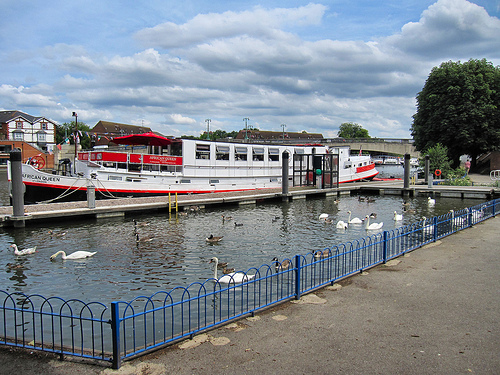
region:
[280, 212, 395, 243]
Geese in the water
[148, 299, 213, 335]
Blue fence around the water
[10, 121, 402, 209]
Boat docked by the pier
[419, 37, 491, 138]
Large tree in background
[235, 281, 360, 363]
Stains on the concrete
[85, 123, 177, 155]
Boat has a red canopy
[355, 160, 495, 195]
Dock leading to the pier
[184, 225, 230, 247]
Goose in the water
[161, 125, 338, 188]
Windows on side of boat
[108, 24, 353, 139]
Sky is filled with clouds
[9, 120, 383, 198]
a large red and white boat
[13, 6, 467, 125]
the clouds in the sky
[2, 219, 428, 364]
a low blue metal rounded fence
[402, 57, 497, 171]
a large tree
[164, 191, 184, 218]
a yellow ladder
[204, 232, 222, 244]
a brown duck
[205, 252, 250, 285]
a white bird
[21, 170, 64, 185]
the black words on the boat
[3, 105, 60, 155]
the white home in the distance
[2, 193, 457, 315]
a body of water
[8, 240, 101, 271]
two swans in water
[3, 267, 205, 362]
fence surrounding water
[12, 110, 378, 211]
boat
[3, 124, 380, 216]
boat docked to a pier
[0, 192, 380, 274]
swans in a body of wter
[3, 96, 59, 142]
apartment building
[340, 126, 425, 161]
bridge that runs over water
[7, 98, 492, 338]
boat by a bier with swans around it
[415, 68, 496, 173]
large bushy tree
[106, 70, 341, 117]
partially cloudy sky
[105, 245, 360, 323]
Blue color metal fencing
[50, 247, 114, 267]
white colour swan in the water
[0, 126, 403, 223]
red with white colour boat in the water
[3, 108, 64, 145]
building behind the boat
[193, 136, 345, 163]
window of the boat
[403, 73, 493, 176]
tree near the lake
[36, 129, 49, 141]
window of the building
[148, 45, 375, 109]
sky with lots of clouds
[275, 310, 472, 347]
road near the lake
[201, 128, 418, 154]
flyover near the lake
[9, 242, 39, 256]
a white swan on water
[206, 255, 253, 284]
a white swan on water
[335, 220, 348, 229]
a white swan on water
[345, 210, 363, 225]
a white swan on water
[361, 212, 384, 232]
a white swan on water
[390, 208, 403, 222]
a white swan on water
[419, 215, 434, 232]
a white swan on water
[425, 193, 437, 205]
a white swan on water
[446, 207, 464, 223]
a white swan on water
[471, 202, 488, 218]
a white swan on water